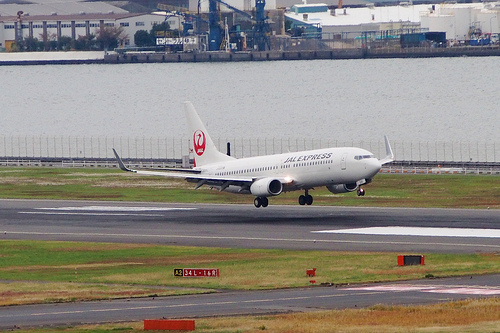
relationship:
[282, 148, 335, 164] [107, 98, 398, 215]
lettering on side of jet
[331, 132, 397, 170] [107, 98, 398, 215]
left wing of jet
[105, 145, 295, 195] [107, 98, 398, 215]
right wing of jet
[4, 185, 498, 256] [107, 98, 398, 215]
runway beneath jet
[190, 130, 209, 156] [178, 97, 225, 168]
symbol on tail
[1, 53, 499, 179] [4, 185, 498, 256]
wall behind runway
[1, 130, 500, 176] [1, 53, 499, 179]
fence in front of wall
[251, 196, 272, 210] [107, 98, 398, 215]
right wheels of jet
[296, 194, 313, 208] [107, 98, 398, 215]
left wheels of jet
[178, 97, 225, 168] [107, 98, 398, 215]
tail of jet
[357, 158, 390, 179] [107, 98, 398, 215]
nose of jet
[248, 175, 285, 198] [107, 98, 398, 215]
engine on jet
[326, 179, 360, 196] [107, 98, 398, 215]
engine on jet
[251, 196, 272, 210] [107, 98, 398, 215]
right wheels on jet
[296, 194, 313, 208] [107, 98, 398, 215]
left wheels on jet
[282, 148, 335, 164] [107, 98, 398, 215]
lettering on jet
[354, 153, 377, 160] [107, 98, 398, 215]
windshield on jet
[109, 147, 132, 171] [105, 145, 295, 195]
tip of right wing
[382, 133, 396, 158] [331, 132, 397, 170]
tip of left wing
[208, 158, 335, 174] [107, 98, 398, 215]
passenger windows on a jet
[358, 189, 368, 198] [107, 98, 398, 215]
front wheel on a jet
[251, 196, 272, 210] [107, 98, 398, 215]
right wheels of a jet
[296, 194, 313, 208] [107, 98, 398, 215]
left wheels of a jet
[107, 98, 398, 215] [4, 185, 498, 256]
jet on a runway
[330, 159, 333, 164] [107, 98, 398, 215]
window on jet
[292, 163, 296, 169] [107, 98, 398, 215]
window on jet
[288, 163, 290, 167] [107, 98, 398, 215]
window on jet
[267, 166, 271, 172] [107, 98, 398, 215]
window on jet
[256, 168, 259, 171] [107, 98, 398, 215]
window on jet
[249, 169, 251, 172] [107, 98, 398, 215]
window on jet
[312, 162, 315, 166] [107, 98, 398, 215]
window on jet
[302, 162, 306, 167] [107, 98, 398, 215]
window on jet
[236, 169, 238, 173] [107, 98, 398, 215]
window on jet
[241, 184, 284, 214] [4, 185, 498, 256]
part on runway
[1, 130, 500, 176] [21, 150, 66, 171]
fence has part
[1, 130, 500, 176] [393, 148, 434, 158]
fence has part